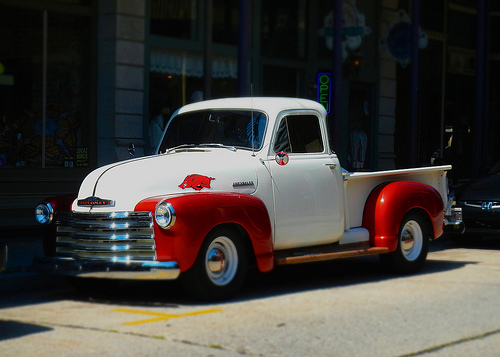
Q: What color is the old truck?
A: The old truck is red and white.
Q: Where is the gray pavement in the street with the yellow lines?
A: The gray pavement with the yellow lines is in front of the truck.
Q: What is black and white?
A: The tires are black and white.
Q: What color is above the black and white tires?
A: The color red.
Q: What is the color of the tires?
A: Black and white.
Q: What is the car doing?
A: Parked.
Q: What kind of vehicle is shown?
A: A truck.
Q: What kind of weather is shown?
A: Sunny.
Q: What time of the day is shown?
A: It is daytime.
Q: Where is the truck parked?
A: At the sidewalk.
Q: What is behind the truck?
A: A car.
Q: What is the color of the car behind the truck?
A: Black.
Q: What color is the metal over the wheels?
A: Red.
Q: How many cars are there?
A: One.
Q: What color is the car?
A: Red and White.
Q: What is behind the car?
A: A restaurant.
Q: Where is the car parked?
A: The street.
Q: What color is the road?
A: Grey.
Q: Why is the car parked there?
A: He is eating inside.